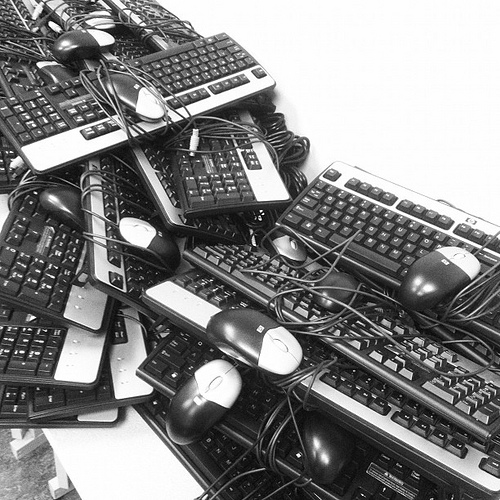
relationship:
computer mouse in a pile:
[97, 69, 170, 122] [2, 0, 500, 499]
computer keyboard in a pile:
[273, 160, 500, 348] [2, 0, 500, 499]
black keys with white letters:
[27, 345, 43, 359] [30, 349, 41, 355]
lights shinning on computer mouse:
[109, 82, 136, 108] [97, 69, 170, 122]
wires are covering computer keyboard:
[77, 167, 174, 275] [76, 145, 185, 322]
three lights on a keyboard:
[59, 335, 82, 373] [1, 158, 113, 336]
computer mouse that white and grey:
[97, 69, 170, 122] [127, 89, 154, 110]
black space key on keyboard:
[330, 233, 404, 276] [273, 160, 500, 348]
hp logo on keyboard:
[464, 215, 477, 225] [273, 160, 500, 348]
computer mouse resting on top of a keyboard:
[97, 69, 170, 122] [1, 30, 276, 176]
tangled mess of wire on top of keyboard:
[77, 167, 174, 275] [76, 145, 185, 322]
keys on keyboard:
[27, 345, 43, 359] [2, 293, 124, 391]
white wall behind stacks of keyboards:
[155, 0, 500, 225] [2, 0, 500, 499]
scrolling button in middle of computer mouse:
[134, 221, 150, 236] [118, 217, 182, 275]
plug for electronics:
[187, 128, 201, 157] [2, 0, 500, 499]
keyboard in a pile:
[1, 158, 113, 336] [2, 0, 500, 499]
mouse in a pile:
[97, 69, 170, 122] [2, 0, 500, 499]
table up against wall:
[2, 0, 500, 499] [155, 0, 500, 225]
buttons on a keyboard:
[39, 282, 53, 296] [1, 158, 113, 336]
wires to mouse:
[77, 167, 174, 275] [118, 217, 182, 275]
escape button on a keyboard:
[324, 167, 341, 180] [273, 160, 500, 348]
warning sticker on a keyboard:
[366, 461, 418, 499] [137, 327, 471, 498]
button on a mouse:
[118, 215, 157, 233] [118, 217, 182, 275]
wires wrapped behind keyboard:
[77, 167, 174, 275] [76, 145, 185, 322]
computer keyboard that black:
[76, 145, 185, 322] [116, 143, 169, 306]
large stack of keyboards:
[2, 0, 500, 499] [131, 159, 499, 499]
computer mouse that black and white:
[97, 69, 170, 122] [129, 82, 157, 109]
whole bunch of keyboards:
[2, 0, 500, 499] [131, 159, 499, 499]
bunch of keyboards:
[2, 0, 500, 499] [131, 159, 499, 499]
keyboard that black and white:
[76, 145, 185, 322] [94, 152, 130, 294]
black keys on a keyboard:
[27, 345, 43, 359] [2, 293, 124, 391]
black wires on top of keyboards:
[0, 0, 205, 62] [2, 0, 500, 499]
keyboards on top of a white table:
[2, 0, 500, 499] [155, 0, 500, 225]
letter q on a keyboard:
[324, 194, 336, 206] [273, 160, 500, 348]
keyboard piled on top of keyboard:
[125, 324, 432, 496] [125, 324, 432, 496]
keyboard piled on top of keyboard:
[125, 324, 432, 496] [187, 235, 484, 436]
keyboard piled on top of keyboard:
[187, 235, 484, 436] [265, 150, 485, 310]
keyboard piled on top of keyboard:
[265, 150, 485, 310] [158, 113, 291, 221]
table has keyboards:
[38, 396, 208, 495] [2, 0, 500, 499]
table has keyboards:
[2, 0, 500, 499] [4, 5, 484, 460]